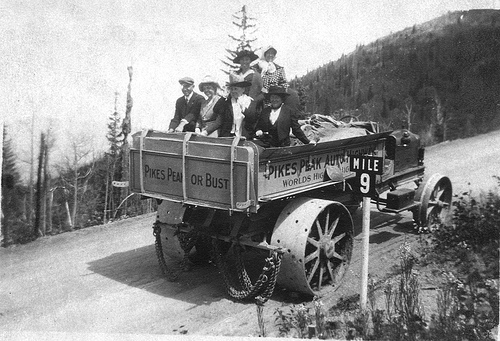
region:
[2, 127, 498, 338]
a steep dirt road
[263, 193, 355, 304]
a large flat wheel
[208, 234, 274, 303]
a large chain hanging off a truck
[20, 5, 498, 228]
a hell past a road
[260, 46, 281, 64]
a bonnet on a woman's head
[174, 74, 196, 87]
a cap on a man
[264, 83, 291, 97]
a black hat on a woman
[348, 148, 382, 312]
a mile sign post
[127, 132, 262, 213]
the tail gate of a truck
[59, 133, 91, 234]
a bare leafless tree by the side of the road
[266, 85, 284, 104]
Black hat on person's head.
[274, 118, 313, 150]
Person wearing black jacket.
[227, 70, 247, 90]
Large hat on person's head.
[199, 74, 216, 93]
Hat on person's head.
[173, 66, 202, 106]
Cap on man's head.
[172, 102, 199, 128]
Man wearing dark jacket.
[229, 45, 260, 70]
Large hat on person's head.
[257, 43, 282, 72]
Person wearing bonnet on head.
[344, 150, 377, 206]
Black sign with white writing.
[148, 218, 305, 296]
Large chain hanging from vehicle.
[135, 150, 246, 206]
sign written on the back of a truck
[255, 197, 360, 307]
wheel on the back of a truck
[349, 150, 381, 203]
mile marker on the road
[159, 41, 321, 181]
a group of people in the back of a truck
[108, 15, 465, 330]
a truck driving up a mountainside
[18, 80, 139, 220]
bare trees line the roadside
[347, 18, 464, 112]
hillside in the distance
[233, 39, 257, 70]
floppy hat on a woman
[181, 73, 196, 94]
cap on a man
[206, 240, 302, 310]
chains on the back of a truck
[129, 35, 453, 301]
large dump truck acrrying men and women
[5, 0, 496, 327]
black and white photograph taken in 19th century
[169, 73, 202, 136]
mannin black suit and beige golf cap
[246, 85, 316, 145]
woman wearing white shirt and black jacket with black hat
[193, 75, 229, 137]
woman in white hat and shawl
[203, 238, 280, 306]
heavy chains on bakc of vehicle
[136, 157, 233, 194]
black lettering on back of truck reading pikes peak or bust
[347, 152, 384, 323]
white post with black 9 mile marker sign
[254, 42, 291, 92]
woman standing on truck wearing polka dot dress with white bow and white hat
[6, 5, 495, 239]
mountians and rough terrain in background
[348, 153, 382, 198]
A mile marker sign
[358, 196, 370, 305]
A metal pole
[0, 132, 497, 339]
A narrow road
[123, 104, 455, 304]
A large truck on the road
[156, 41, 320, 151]
A group of people in the back of a truck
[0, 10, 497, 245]
A large wooded area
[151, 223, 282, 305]
some chains on the back of a truck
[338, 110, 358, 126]
A black steering wheel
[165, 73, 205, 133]
A man in a white shirt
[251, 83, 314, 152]
A woman in a jacket